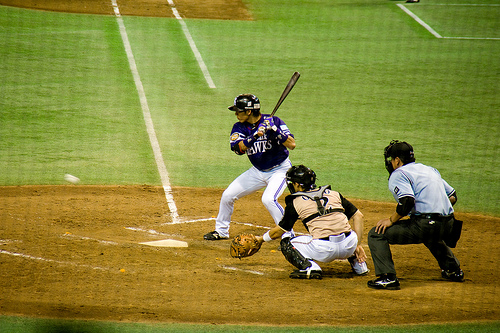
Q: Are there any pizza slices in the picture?
A: No, there are no pizza slices.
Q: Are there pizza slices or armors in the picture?
A: No, there are no pizza slices or armors.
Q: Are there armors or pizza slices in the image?
A: No, there are no pizza slices or armors.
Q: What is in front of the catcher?
A: The home plate is in front of the catcher.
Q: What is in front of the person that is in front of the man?
A: The home plate is in front of the catcher.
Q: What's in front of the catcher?
A: The home plate is in front of the catcher.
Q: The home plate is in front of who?
A: The home plate is in front of the catcher.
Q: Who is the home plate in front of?
A: The home plate is in front of the catcher.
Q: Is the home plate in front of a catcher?
A: Yes, the home plate is in front of a catcher.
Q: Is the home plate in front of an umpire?
A: No, the home plate is in front of a catcher.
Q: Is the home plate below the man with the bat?
A: Yes, the home plate is below the man.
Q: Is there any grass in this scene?
A: Yes, there is grass.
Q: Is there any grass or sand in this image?
A: Yes, there is grass.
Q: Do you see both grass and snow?
A: No, there is grass but no snow.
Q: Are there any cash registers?
A: No, there are no cash registers.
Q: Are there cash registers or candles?
A: No, there are no cash registers or candles.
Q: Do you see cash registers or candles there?
A: No, there are no cash registers or candles.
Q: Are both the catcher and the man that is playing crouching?
A: Yes, both the catcher and the man are crouching.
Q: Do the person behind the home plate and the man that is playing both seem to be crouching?
A: Yes, both the catcher and the man are crouching.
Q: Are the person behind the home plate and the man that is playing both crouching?
A: Yes, both the catcher and the man are crouching.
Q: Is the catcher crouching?
A: Yes, the catcher is crouching.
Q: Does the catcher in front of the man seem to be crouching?
A: Yes, the catcher is crouching.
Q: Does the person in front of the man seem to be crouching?
A: Yes, the catcher is crouching.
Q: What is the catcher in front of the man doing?
A: The catcher is crouching.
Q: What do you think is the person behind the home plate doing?
A: The catcher is crouching.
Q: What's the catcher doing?
A: The catcher is crouching.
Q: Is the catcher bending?
A: No, the catcher is crouching.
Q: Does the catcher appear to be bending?
A: No, the catcher is crouching.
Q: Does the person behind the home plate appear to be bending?
A: No, the catcher is crouching.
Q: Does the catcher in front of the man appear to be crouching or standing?
A: The catcher is crouching.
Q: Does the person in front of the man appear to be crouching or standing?
A: The catcher is crouching.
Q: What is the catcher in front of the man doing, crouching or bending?
A: The catcher is crouching.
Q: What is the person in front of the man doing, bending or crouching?
A: The catcher is crouching.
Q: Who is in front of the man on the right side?
A: The catcher is in front of the man.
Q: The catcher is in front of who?
A: The catcher is in front of the man.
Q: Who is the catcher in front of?
A: The catcher is in front of the man.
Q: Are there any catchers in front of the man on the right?
A: Yes, there is a catcher in front of the man.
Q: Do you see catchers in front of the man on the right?
A: Yes, there is a catcher in front of the man.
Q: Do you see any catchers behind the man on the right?
A: No, the catcher is in front of the man.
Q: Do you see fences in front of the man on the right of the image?
A: No, there is a catcher in front of the man.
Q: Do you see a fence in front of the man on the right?
A: No, there is a catcher in front of the man.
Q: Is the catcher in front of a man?
A: Yes, the catcher is in front of a man.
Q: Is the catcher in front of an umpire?
A: No, the catcher is in front of a man.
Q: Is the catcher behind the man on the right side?
A: No, the catcher is in front of the man.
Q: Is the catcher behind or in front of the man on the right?
A: The catcher is in front of the man.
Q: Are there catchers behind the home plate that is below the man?
A: Yes, there is a catcher behind the home plate.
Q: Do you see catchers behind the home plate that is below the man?
A: Yes, there is a catcher behind the home plate.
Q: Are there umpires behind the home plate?
A: No, there is a catcher behind the home plate.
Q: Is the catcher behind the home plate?
A: Yes, the catcher is behind the home plate.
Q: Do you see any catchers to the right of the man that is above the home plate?
A: Yes, there is a catcher to the right of the man.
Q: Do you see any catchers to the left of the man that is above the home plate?
A: No, the catcher is to the right of the man.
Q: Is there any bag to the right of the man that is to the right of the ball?
A: No, there is a catcher to the right of the man.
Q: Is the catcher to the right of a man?
A: Yes, the catcher is to the right of a man.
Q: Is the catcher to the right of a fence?
A: No, the catcher is to the right of a man.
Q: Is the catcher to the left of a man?
A: No, the catcher is to the right of a man.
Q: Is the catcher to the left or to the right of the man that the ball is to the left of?
A: The catcher is to the right of the man.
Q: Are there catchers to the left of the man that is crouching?
A: Yes, there is a catcher to the left of the man.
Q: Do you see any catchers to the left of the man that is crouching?
A: Yes, there is a catcher to the left of the man.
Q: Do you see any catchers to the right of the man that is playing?
A: No, the catcher is to the left of the man.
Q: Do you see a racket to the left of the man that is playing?
A: No, there is a catcher to the left of the man.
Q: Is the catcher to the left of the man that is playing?
A: Yes, the catcher is to the left of the man.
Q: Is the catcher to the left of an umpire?
A: No, the catcher is to the left of the man.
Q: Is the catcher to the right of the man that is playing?
A: No, the catcher is to the left of the man.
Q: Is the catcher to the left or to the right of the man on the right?
A: The catcher is to the left of the man.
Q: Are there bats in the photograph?
A: Yes, there is a bat.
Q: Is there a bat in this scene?
A: Yes, there is a bat.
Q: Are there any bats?
A: Yes, there is a bat.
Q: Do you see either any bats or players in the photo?
A: Yes, there is a bat.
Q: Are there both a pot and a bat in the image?
A: No, there is a bat but no pots.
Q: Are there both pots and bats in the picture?
A: No, there is a bat but no pots.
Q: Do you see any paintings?
A: No, there are no paintings.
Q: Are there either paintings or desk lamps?
A: No, there are no paintings or desk lamps.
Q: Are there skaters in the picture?
A: No, there are no skaters.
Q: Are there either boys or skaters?
A: No, there are no skaters or boys.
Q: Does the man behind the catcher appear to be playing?
A: Yes, the man is playing.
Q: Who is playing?
A: The man is playing.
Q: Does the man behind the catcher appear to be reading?
A: No, the man is playing.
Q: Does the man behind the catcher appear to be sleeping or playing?
A: The man is playing.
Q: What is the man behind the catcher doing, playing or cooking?
A: The man is playing.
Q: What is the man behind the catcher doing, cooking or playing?
A: The man is playing.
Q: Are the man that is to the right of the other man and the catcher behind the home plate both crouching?
A: Yes, both the man and the catcher are crouching.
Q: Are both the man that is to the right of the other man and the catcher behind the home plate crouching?
A: Yes, both the man and the catcher are crouching.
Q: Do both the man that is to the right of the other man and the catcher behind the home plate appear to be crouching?
A: Yes, both the man and the catcher are crouching.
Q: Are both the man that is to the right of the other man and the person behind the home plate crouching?
A: Yes, both the man and the catcher are crouching.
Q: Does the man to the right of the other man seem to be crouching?
A: Yes, the man is crouching.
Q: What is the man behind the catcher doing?
A: The man is crouching.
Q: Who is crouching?
A: The man is crouching.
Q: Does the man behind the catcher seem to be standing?
A: No, the man is crouching.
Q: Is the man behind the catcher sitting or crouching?
A: The man is crouching.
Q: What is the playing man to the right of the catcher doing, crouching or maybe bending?
A: The man is crouching.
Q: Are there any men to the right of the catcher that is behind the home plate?
A: Yes, there is a man to the right of the catcher.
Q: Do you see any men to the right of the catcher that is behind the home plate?
A: Yes, there is a man to the right of the catcher.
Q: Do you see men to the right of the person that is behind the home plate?
A: Yes, there is a man to the right of the catcher.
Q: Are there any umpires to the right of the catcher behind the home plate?
A: No, there is a man to the right of the catcher.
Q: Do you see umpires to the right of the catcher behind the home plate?
A: No, there is a man to the right of the catcher.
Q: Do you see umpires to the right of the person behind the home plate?
A: No, there is a man to the right of the catcher.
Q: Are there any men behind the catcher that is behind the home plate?
A: Yes, there is a man behind the catcher.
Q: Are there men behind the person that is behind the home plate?
A: Yes, there is a man behind the catcher.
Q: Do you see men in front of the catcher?
A: No, the man is behind the catcher.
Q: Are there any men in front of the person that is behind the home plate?
A: No, the man is behind the catcher.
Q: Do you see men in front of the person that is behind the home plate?
A: No, the man is behind the catcher.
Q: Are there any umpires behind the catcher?
A: No, there is a man behind the catcher.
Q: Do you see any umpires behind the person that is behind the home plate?
A: No, there is a man behind the catcher.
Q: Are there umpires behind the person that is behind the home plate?
A: No, there is a man behind the catcher.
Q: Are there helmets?
A: Yes, there is a helmet.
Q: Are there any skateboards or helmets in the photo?
A: Yes, there is a helmet.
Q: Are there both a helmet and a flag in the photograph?
A: No, there is a helmet but no flags.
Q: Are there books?
A: No, there are no books.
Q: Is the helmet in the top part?
A: Yes, the helmet is in the top of the image.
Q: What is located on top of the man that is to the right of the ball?
A: The helmet is on top of the man.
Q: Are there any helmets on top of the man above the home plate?
A: Yes, there is a helmet on top of the man.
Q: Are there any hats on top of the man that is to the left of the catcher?
A: No, there is a helmet on top of the man.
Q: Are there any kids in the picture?
A: No, there are no kids.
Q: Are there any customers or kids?
A: No, there are no kids or customers.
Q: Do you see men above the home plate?
A: Yes, there is a man above the home plate.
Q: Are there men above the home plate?
A: Yes, there is a man above the home plate.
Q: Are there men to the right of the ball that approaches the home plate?
A: Yes, there is a man to the right of the ball.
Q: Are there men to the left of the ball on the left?
A: No, the man is to the right of the ball.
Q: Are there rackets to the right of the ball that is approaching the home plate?
A: No, there is a man to the right of the ball.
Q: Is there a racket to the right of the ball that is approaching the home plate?
A: No, there is a man to the right of the ball.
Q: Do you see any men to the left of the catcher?
A: Yes, there is a man to the left of the catcher.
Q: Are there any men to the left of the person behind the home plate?
A: Yes, there is a man to the left of the catcher.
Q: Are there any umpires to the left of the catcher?
A: No, there is a man to the left of the catcher.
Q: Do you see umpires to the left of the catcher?
A: No, there is a man to the left of the catcher.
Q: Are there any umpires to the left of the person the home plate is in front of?
A: No, there is a man to the left of the catcher.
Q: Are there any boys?
A: No, there are no boys.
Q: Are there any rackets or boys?
A: No, there are no boys or rackets.